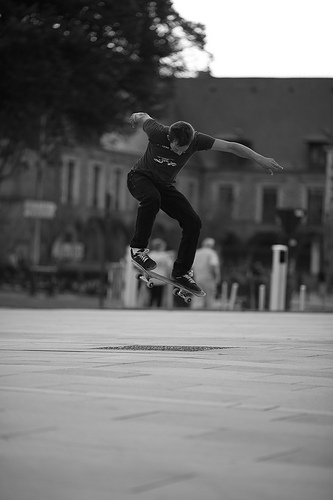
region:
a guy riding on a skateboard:
[125, 111, 281, 301]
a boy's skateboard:
[136, 263, 205, 303]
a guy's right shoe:
[129, 247, 155, 268]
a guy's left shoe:
[172, 274, 203, 299]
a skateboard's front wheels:
[173, 290, 193, 304]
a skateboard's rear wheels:
[135, 273, 157, 289]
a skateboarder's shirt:
[137, 117, 215, 187]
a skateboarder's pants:
[127, 172, 200, 272]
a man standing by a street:
[192, 238, 218, 309]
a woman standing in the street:
[149, 239, 176, 307]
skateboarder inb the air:
[125, 111, 281, 293]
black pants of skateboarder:
[126, 170, 200, 279]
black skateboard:
[130, 262, 201, 300]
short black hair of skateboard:
[166, 120, 193, 146]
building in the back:
[1, 70, 332, 310]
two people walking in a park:
[144, 239, 221, 306]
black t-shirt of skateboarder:
[132, 118, 209, 184]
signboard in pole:
[23, 199, 56, 258]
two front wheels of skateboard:
[133, 269, 157, 295]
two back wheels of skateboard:
[170, 287, 194, 303]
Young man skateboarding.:
[112, 108, 288, 308]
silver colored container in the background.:
[267, 240, 289, 311]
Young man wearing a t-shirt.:
[125, 106, 220, 186]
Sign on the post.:
[21, 194, 59, 221]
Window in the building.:
[254, 180, 280, 225]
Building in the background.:
[0, 73, 331, 289]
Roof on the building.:
[83, 70, 329, 173]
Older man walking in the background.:
[188, 236, 224, 312]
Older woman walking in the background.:
[139, 236, 177, 305]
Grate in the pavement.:
[86, 340, 236, 354]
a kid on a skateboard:
[53, 87, 301, 324]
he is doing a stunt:
[88, 96, 241, 297]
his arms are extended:
[96, 96, 318, 180]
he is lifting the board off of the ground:
[71, 156, 234, 305]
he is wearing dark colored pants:
[110, 164, 211, 271]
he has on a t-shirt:
[131, 117, 202, 187]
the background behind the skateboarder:
[22, 103, 319, 298]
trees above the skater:
[6, 7, 192, 104]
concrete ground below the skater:
[40, 317, 325, 444]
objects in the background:
[229, 205, 316, 307]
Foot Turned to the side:
[126, 242, 159, 273]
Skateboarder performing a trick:
[115, 106, 284, 306]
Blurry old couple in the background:
[137, 232, 225, 311]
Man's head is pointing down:
[160, 116, 199, 159]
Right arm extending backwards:
[122, 107, 168, 148]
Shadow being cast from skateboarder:
[0, 345, 98, 354]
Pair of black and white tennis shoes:
[128, 242, 203, 295]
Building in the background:
[0, 68, 332, 318]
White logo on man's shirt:
[151, 153, 178, 169]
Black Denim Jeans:
[123, 166, 203, 283]